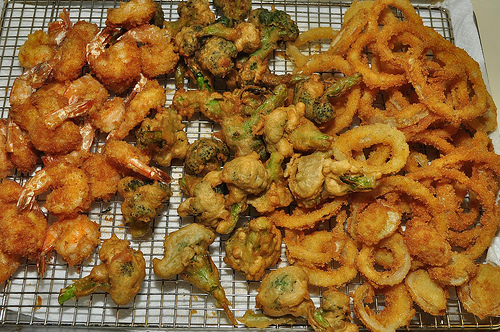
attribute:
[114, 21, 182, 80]
shrimp — fried, hot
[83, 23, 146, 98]
shrimp — fried, hot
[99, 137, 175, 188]
shrimp — fried, hot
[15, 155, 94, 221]
shrimp — fried, hot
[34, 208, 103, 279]
shrimp — fried, hot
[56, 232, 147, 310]
broccoli — fried, cooked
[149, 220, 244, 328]
broccoli — fried, cooked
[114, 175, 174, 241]
broccoli — fried, cooked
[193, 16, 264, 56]
broccoli — fried, cooked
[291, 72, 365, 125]
broccoli — fried, cooked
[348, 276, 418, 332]
onion — fried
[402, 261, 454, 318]
onion — fried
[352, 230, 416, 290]
onion — fried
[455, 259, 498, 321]
onion — fried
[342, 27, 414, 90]
onion — fried